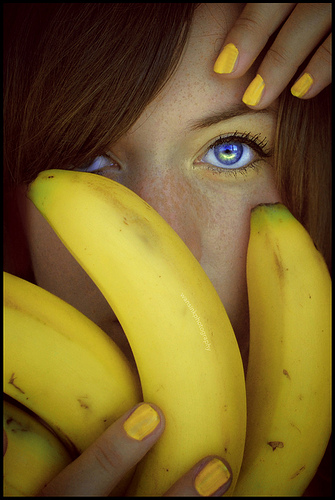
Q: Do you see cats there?
A: No, there are no cats.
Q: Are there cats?
A: No, there are no cats.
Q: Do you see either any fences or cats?
A: No, there are no cats or fences.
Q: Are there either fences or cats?
A: No, there are no cats or fences.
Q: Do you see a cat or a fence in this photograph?
A: No, there are no cats or fences.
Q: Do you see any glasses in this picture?
A: No, there are no glasses.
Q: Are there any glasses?
A: No, there are no glasses.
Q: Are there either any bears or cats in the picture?
A: No, there are no cats or bears.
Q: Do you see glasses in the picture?
A: No, there are no glasses.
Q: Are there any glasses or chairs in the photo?
A: No, there are no glasses or chairs.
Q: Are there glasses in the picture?
A: No, there are no glasses.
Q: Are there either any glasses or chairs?
A: No, there are no glasses or chairs.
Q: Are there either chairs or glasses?
A: No, there are no glasses or chairs.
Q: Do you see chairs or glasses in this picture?
A: No, there are no glasses or chairs.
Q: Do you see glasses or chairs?
A: No, there are no glasses or chairs.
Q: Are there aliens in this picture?
A: No, there are no aliens.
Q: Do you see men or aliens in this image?
A: No, there are no aliens or men.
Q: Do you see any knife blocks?
A: No, there are no knife blocks.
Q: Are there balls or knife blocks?
A: No, there are no knife blocks or balls.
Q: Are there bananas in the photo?
A: Yes, there is a banana.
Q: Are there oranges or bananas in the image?
A: Yes, there is a banana.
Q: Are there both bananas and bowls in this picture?
A: No, there is a banana but no bowls.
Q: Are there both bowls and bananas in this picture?
A: No, there is a banana but no bowls.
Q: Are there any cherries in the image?
A: No, there are no cherries.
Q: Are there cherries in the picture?
A: No, there are no cherries.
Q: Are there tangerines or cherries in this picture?
A: No, there are no cherries or tangerines.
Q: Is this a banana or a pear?
A: This is a banana.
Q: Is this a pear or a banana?
A: This is a banana.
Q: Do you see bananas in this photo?
A: Yes, there is a banana.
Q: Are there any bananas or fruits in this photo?
A: Yes, there is a banana.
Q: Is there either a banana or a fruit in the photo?
A: Yes, there is a banana.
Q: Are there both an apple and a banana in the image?
A: No, there is a banana but no apples.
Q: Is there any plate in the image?
A: No, there are no plates.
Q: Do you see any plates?
A: No, there are no plates.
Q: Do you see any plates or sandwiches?
A: No, there are no plates or sandwiches.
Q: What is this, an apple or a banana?
A: This is a banana.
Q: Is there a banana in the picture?
A: Yes, there is a banana.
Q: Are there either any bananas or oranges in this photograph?
A: Yes, there is a banana.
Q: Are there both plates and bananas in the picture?
A: No, there is a banana but no plates.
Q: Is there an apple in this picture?
A: No, there are no apples.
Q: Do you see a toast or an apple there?
A: No, there are no apples or toasts.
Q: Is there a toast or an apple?
A: No, there are no apples or toasts.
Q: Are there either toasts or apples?
A: No, there are no apples or toasts.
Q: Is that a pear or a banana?
A: That is a banana.